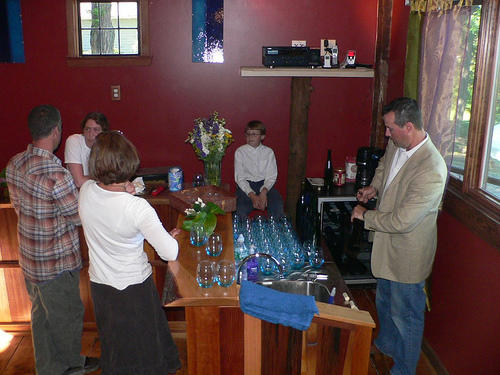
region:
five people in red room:
[18, 81, 433, 371]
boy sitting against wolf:
[220, 114, 284, 222]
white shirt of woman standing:
[73, 180, 164, 283]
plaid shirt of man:
[5, 146, 80, 262]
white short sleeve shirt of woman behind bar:
[65, 117, 112, 184]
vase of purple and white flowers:
[185, 114, 235, 188]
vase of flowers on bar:
[182, 192, 217, 244]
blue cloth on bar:
[235, 277, 318, 327]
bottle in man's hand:
[345, 184, 368, 244]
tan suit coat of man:
[360, 144, 437, 272]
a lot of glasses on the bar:
[220, 214, 335, 277]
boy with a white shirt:
[228, 115, 281, 192]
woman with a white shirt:
[77, 135, 173, 288]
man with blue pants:
[373, 268, 498, 358]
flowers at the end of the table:
[182, 113, 238, 192]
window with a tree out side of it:
[62, 5, 146, 60]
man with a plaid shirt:
[16, 133, 83, 289]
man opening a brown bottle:
[336, 177, 403, 254]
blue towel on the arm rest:
[232, 272, 336, 334]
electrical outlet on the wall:
[99, 70, 138, 106]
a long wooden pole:
[280, 75, 318, 213]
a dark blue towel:
[238, 279, 316, 330]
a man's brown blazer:
[369, 135, 449, 282]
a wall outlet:
[110, 80, 125, 101]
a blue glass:
[309, 246, 324, 267]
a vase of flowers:
[185, 112, 237, 184]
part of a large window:
[409, 5, 481, 178]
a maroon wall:
[228, 0, 373, 46]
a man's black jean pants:
[26, 270, 83, 372]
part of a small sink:
[255, 274, 327, 304]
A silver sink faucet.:
[236, 251, 288, 286]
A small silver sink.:
[252, 272, 352, 314]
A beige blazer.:
[363, 135, 443, 281]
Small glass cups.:
[189, 209, 329, 294]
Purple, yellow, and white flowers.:
[187, 107, 234, 167]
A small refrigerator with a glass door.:
[304, 179, 394, 286]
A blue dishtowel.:
[237, 275, 317, 332]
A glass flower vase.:
[203, 161, 222, 189]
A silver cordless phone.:
[329, 42, 338, 69]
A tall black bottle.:
[324, 146, 336, 184]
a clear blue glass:
[194, 260, 212, 290]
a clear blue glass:
[215, 260, 233, 289]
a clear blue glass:
[202, 233, 222, 260]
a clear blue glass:
[187, 225, 205, 247]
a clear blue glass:
[309, 245, 324, 269]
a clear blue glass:
[300, 240, 314, 262]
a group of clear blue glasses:
[232, 211, 297, 276]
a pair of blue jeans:
[376, 273, 426, 370]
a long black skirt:
[87, 280, 183, 373]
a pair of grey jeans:
[19, 269, 81, 372]